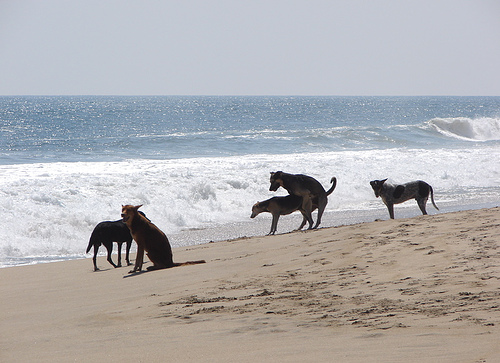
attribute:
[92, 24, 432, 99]
skies — grey, pverhead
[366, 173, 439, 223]
dog — black, white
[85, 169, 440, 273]
brown dogs — black, white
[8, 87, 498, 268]
water — blue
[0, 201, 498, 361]
beach — sandy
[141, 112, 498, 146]
waves — small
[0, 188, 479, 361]
beach — sandy